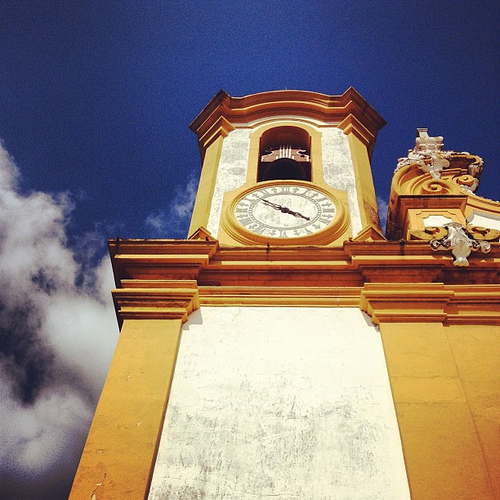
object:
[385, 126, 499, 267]
achitecture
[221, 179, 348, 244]
clock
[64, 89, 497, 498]
tower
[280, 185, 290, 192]
roman numeral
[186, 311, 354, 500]
space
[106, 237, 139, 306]
building corner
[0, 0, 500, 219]
skies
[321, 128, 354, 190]
design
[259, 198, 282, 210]
clock arm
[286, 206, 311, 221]
clock arm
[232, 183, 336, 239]
clock interior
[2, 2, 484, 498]
photo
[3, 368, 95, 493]
cloud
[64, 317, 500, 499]
wall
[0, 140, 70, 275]
cloud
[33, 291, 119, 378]
cloud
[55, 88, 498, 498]
building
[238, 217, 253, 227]
roman numerals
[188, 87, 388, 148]
top